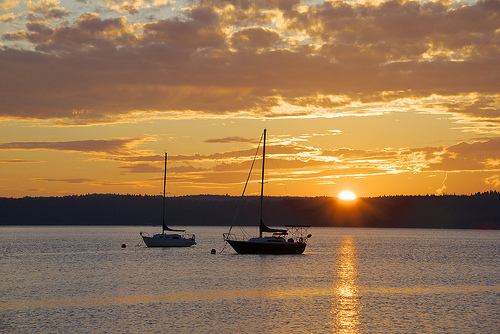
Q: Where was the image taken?
A: It was taken at the shore.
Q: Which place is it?
A: It is a shore.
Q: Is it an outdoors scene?
A: Yes, it is outdoors.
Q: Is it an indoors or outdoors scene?
A: It is outdoors.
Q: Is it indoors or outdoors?
A: It is outdoors.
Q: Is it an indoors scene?
A: No, it is outdoors.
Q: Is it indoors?
A: No, it is outdoors.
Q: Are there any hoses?
A: No, there are no hoses.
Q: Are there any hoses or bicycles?
A: No, there are no hoses or bicycles.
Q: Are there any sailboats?
A: Yes, there is a sailboat.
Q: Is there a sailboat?
A: Yes, there is a sailboat.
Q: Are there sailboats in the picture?
A: Yes, there is a sailboat.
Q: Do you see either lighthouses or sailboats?
A: Yes, there is a sailboat.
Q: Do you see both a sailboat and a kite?
A: No, there is a sailboat but no kites.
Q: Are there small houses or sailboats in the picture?
A: Yes, there is a small sailboat.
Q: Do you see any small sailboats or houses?
A: Yes, there is a small sailboat.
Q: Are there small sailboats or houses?
A: Yes, there is a small sailboat.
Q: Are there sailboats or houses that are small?
A: Yes, the sailboat is small.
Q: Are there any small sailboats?
A: Yes, there is a small sailboat.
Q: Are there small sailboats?
A: Yes, there is a small sailboat.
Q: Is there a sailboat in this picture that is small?
A: Yes, there is a sailboat that is small.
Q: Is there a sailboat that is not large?
A: Yes, there is a small sailboat.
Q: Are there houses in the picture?
A: No, there are no houses.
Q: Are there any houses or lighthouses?
A: No, there are no houses or lighthouses.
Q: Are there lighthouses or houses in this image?
A: No, there are no houses or lighthouses.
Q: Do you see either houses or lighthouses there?
A: No, there are no houses or lighthouses.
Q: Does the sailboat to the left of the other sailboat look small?
A: Yes, the sailboat is small.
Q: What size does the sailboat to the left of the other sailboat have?
A: The sailboat has small size.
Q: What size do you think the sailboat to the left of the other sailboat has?
A: The sailboat has small size.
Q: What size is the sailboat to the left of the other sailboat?
A: The sailboat is small.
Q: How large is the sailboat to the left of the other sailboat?
A: The sailboat is small.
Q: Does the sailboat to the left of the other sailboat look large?
A: No, the sailboat is small.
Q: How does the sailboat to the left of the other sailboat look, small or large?
A: The sailboat is small.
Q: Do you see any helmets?
A: No, there are no helmets.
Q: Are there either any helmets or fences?
A: No, there are no helmets or fences.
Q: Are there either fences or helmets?
A: No, there are no helmets or fences.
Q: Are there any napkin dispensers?
A: No, there are no napkin dispensers.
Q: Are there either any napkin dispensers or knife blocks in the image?
A: No, there are no napkin dispensers or knife blocks.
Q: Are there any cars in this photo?
A: No, there are no cars.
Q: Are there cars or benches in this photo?
A: No, there are no cars or benches.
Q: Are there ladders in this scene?
A: No, there are no ladders.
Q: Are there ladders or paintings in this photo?
A: No, there are no ladders or paintings.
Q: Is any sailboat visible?
A: Yes, there is a sailboat.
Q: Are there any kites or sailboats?
A: Yes, there is a sailboat.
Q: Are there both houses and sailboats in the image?
A: No, there is a sailboat but no houses.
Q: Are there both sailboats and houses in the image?
A: No, there is a sailboat but no houses.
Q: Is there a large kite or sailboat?
A: Yes, there is a large sailboat.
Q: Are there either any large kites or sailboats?
A: Yes, there is a large sailboat.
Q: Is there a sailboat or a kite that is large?
A: Yes, the sailboat is large.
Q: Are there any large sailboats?
A: Yes, there is a large sailboat.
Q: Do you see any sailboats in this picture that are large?
A: Yes, there is a sailboat that is large.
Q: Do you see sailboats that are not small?
A: Yes, there is a large sailboat.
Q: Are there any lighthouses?
A: No, there are no lighthouses.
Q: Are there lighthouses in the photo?
A: No, there are no lighthouses.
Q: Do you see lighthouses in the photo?
A: No, there are no lighthouses.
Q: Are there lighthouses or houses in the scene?
A: No, there are no lighthouses or houses.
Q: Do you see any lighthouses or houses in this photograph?
A: No, there are no lighthouses or houses.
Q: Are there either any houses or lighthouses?
A: No, there are no lighthouses or houses.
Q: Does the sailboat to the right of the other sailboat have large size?
A: Yes, the sailboat is large.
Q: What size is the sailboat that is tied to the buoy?
A: The sailboat is large.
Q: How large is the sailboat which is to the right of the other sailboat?
A: The sailboat is large.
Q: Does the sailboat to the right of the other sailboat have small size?
A: No, the sailboat is large.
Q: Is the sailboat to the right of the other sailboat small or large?
A: The sailboat is large.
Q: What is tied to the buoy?
A: The sailboat is tied to the buoy.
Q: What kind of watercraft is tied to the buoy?
A: The watercraft is a sailboat.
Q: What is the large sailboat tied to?
A: The sailboat is tied to the buoy.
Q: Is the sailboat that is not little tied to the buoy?
A: Yes, the sailboat is tied to the buoy.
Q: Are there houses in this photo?
A: No, there are no houses.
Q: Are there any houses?
A: No, there are no houses.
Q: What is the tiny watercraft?
A: The watercraft is boats.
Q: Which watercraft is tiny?
A: The watercraft is boats.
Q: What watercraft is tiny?
A: The watercraft is boats.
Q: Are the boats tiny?
A: Yes, the boats are tiny.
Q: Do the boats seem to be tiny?
A: Yes, the boats are tiny.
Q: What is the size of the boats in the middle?
A: The boats are tiny.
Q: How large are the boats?
A: The boats are tiny.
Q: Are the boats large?
A: No, the boats are tiny.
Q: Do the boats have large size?
A: No, the boats are tiny.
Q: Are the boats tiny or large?
A: The boats are tiny.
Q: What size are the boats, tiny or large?
A: The boats are tiny.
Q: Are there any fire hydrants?
A: No, there are no fire hydrants.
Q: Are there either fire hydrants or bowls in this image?
A: No, there are no fire hydrants or bowls.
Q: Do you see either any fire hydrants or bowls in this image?
A: No, there are no fire hydrants or bowls.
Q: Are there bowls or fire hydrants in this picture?
A: No, there are no fire hydrants or bowls.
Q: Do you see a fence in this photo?
A: No, there are no fences.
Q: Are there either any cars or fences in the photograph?
A: No, there are no fences or cars.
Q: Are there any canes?
A: No, there are no canes.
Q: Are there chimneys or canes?
A: No, there are no canes or chimneys.